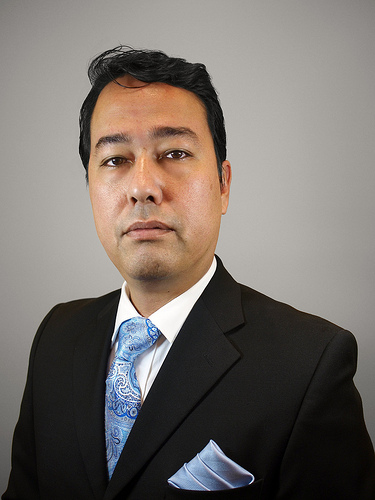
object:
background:
[1, 0, 363, 498]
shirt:
[104, 255, 217, 480]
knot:
[115, 316, 162, 363]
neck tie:
[104, 317, 162, 481]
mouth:
[124, 220, 174, 239]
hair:
[79, 44, 227, 185]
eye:
[167, 151, 190, 159]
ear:
[221, 160, 232, 214]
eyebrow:
[148, 125, 198, 142]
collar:
[111, 256, 217, 348]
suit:
[0, 254, 375, 499]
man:
[0, 45, 375, 500]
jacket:
[0, 253, 375, 500]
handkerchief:
[167, 439, 255, 491]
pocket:
[162, 479, 262, 500]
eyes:
[105, 157, 129, 166]